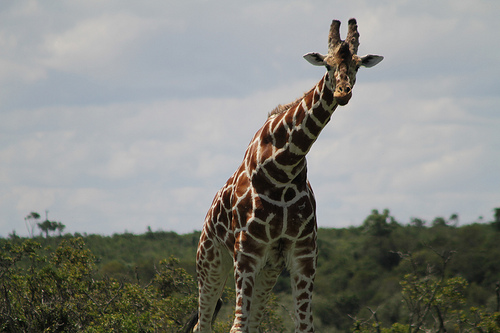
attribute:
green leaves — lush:
[38, 231, 161, 313]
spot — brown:
[280, 192, 316, 241]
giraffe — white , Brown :
[192, 10, 397, 329]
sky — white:
[80, 50, 165, 123]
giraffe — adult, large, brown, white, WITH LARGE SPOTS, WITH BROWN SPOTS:
[180, 17, 392, 332]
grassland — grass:
[1, 208, 499, 331]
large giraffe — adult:
[189, 17, 384, 331]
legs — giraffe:
[222, 257, 322, 327]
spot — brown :
[279, 184, 301, 204]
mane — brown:
[249, 73, 314, 125]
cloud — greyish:
[49, 17, 150, 71]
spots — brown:
[247, 164, 316, 245]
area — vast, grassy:
[0, 222, 475, 331]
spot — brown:
[286, 101, 311, 135]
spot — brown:
[228, 168, 253, 200]